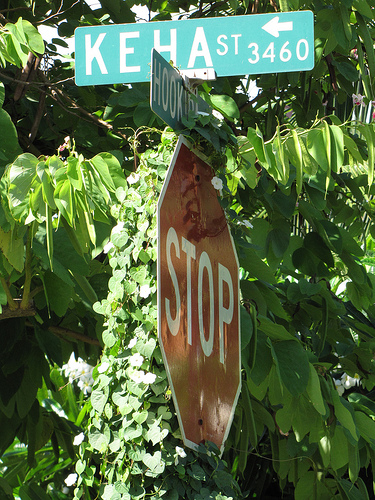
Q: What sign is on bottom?
A: Stop sign.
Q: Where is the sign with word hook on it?
A: In the middle.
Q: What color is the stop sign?
A: Red.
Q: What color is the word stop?
A: White.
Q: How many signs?
A: 3.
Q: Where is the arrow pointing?
A: Left.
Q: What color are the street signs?
A: Green.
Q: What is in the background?
A: Trees.